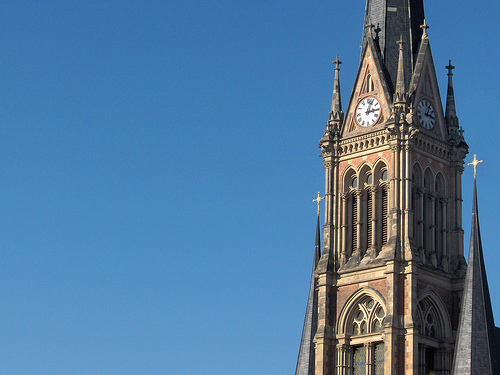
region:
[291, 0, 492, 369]
A large clock tower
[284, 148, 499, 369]
a pair of spires next to the tower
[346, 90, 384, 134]
A clock on the tower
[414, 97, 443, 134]
A clock on the tower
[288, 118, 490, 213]
crosses on top of the spires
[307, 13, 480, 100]
A group of spires next to the clocks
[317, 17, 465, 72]
crosses on top of the spires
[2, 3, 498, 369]
A clear, blue sky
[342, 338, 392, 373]
Some windows on the tower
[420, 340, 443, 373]
Some windows on the tower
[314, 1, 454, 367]
church steeple is tall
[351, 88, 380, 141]
church has clock on tower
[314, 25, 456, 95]
church has decorative tops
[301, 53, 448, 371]
church is red and brown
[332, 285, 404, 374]
church has rounded windows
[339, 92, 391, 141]
clock uses roman numerals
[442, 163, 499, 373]
spears on tower are grey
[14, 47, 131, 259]
sky is blue and cloudless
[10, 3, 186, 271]
sky is clear and blue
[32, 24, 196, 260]
sky is blue and sunny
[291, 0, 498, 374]
tall clack tower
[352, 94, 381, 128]
round clock face with roman numerals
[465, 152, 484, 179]
decorative cross on spire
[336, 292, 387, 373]
ornate, arched window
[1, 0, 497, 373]
clear, deep blue sky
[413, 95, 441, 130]
clock face in the shadow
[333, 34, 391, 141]
triangular panel around clock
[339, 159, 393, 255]
three skinny window arches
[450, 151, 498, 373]
spire next to clock tower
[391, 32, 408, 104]
mini spire between clocks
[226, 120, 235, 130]
part of the sky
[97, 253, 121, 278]
section of the sky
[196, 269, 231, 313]
part of blue sky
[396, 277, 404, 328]
edge of a building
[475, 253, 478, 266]
roof of a building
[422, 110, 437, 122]
part of a clock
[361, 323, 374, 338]
window of a building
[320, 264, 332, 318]
side of a building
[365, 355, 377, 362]
part of the window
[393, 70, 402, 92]
part of a tower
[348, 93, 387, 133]
Clock on front of building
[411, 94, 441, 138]
Clock on side of building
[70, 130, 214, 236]
Cloudless clear blue sky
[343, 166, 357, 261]
First window on front of building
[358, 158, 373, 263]
Second window on front of building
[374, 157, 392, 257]
Third window on front of building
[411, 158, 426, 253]
First window on side of building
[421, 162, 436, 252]
Second window on side of building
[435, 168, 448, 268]
Third window on side of building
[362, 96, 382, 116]
Clock hands on front of building